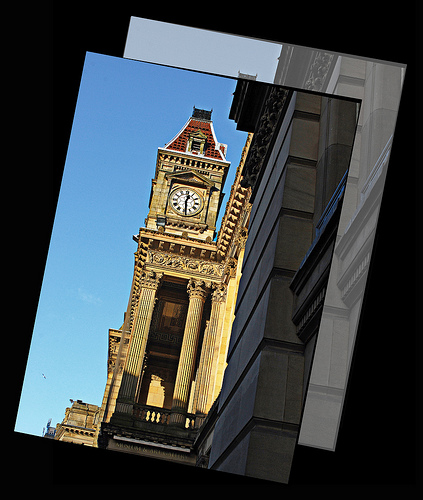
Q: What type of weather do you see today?
A: It is clear.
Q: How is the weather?
A: It is clear.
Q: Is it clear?
A: Yes, it is clear.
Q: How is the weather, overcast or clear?
A: It is clear.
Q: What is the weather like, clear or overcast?
A: It is clear.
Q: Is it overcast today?
A: No, it is clear.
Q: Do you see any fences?
A: No, there are no fences.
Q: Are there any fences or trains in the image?
A: No, there are no fences or trains.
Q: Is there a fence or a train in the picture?
A: No, there are no fences or trains.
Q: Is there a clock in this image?
A: Yes, there is a clock.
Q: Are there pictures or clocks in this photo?
A: Yes, there is a clock.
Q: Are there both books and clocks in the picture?
A: No, there is a clock but no books.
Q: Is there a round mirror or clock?
A: Yes, there is a round clock.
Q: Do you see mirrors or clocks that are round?
A: Yes, the clock is round.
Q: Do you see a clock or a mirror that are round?
A: Yes, the clock is round.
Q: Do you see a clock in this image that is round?
A: Yes, there is a round clock.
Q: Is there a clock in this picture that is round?
A: Yes, there is a clock that is round.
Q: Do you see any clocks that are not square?
A: Yes, there is a round clock.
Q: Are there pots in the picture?
A: No, there are no pots.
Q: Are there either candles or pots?
A: No, there are no pots or candles.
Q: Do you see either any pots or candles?
A: No, there are no pots or candles.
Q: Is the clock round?
A: Yes, the clock is round.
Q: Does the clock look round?
A: Yes, the clock is round.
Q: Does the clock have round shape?
A: Yes, the clock is round.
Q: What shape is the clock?
A: The clock is round.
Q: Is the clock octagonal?
A: No, the clock is round.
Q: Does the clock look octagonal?
A: No, the clock is round.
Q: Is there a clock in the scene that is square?
A: No, there is a clock but it is round.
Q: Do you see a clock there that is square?
A: No, there is a clock but it is round.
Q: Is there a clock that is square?
A: No, there is a clock but it is round.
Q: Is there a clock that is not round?
A: No, there is a clock but it is round.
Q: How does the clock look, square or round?
A: The clock is round.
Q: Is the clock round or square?
A: The clock is round.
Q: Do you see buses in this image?
A: No, there are no buses.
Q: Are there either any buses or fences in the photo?
A: No, there are no buses or fences.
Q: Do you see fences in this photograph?
A: No, there are no fences.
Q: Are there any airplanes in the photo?
A: No, there are no airplanes.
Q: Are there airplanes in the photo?
A: No, there are no airplanes.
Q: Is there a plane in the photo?
A: No, there are no airplanes.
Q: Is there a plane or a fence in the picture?
A: No, there are no airplanes or fences.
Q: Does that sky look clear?
A: Yes, the sky is clear.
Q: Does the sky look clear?
A: Yes, the sky is clear.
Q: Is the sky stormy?
A: No, the sky is clear.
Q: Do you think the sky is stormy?
A: No, the sky is clear.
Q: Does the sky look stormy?
A: No, the sky is clear.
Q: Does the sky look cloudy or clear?
A: The sky is clear.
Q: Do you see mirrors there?
A: No, there are no mirrors.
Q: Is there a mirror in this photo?
A: No, there are no mirrors.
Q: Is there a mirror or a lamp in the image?
A: No, there are no mirrors or lamps.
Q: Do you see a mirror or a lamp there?
A: No, there are no mirrors or lamps.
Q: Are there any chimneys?
A: No, there are no chimneys.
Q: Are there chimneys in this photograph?
A: No, there are no chimneys.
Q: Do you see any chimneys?
A: No, there are no chimneys.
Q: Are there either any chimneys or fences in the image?
A: No, there are no chimneys or fences.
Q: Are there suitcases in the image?
A: No, there are no suitcases.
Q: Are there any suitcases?
A: No, there are no suitcases.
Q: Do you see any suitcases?
A: No, there are no suitcases.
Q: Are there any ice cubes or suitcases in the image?
A: No, there are no suitcases or ice cubes.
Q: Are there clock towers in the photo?
A: Yes, there is a clock tower.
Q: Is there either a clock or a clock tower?
A: Yes, there is a clock tower.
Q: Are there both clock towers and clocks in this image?
A: Yes, there are both a clock tower and a clock.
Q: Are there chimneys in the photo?
A: No, there are no chimneys.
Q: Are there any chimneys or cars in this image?
A: No, there are no chimneys or cars.